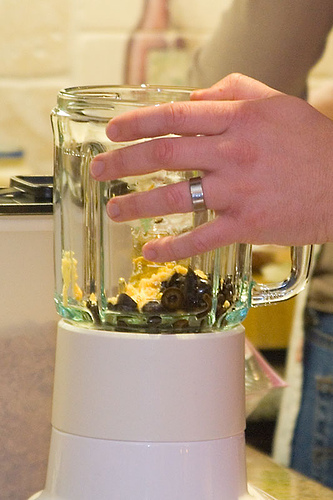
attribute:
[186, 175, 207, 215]
ring — silver, wedding band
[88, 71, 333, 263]
hand — left hand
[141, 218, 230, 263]
finger — pinky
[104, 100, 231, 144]
finger — index finger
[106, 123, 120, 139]
fingernail — short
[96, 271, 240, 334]
olives — black, cut, sliced up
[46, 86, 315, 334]
blender — glass, open, electric, clear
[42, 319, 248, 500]
bottom — white, plastic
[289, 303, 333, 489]
jeans — blue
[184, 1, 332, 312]
shirt — long sleeved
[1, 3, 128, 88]
wall — cream, tiled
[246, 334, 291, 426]
bag — plastic, transparent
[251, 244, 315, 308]
handle — glass, transparent